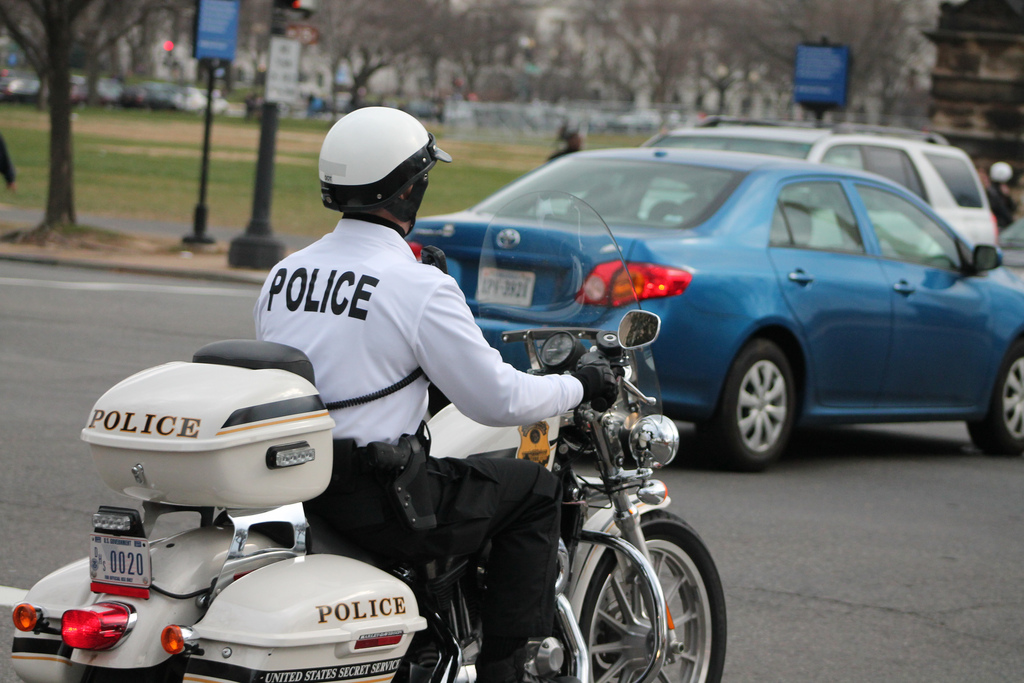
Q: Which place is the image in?
A: It is at the road.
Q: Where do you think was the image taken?
A: It was taken at the road.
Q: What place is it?
A: It is a road.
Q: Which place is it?
A: It is a road.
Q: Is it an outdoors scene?
A: Yes, it is outdoors.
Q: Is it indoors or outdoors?
A: It is outdoors.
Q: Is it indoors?
A: No, it is outdoors.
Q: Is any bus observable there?
A: No, there are no buses.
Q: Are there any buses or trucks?
A: No, there are no buses or trucks.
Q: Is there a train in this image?
A: No, there are no trains.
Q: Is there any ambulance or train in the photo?
A: No, there are no trains or ambulances.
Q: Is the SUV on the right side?
A: Yes, the SUV is on the right of the image.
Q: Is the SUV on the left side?
A: No, the SUV is on the right of the image.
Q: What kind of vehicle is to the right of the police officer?
A: The vehicle is a SUV.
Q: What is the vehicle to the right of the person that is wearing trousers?
A: The vehicle is a SUV.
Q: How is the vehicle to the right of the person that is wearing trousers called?
A: The vehicle is a SUV.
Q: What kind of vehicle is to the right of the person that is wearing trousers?
A: The vehicle is a SUV.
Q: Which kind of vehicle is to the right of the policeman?
A: The vehicle is a SUV.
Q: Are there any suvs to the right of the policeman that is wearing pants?
A: Yes, there is a SUV to the right of the policeman.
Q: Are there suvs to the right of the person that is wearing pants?
A: Yes, there is a SUV to the right of the policeman.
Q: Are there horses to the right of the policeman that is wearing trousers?
A: No, there is a SUV to the right of the policeman.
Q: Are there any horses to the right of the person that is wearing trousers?
A: No, there is a SUV to the right of the policeman.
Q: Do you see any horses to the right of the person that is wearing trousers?
A: No, there is a SUV to the right of the policeman.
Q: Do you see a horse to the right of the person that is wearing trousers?
A: No, there is a SUV to the right of the policeman.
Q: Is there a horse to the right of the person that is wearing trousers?
A: No, there is a SUV to the right of the policeman.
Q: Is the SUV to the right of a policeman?
A: Yes, the SUV is to the right of a policeman.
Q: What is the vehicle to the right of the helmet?
A: The vehicle is a SUV.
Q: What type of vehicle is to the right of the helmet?
A: The vehicle is a SUV.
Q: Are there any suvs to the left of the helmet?
A: No, the SUV is to the right of the helmet.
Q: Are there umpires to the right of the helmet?
A: No, there is a SUV to the right of the helmet.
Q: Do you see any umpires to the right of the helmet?
A: No, there is a SUV to the right of the helmet.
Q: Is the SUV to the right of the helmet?
A: Yes, the SUV is to the right of the helmet.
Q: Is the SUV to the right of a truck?
A: No, the SUV is to the right of the helmet.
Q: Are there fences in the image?
A: No, there are no fences.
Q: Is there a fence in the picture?
A: No, there are no fences.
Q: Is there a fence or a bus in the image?
A: No, there are no fences or buses.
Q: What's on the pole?
A: The sign is on the pole.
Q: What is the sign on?
A: The sign is on the pole.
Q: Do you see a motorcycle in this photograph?
A: Yes, there is a motorcycle.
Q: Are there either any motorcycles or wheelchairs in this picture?
A: Yes, there is a motorcycle.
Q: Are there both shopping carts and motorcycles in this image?
A: No, there is a motorcycle but no shopping carts.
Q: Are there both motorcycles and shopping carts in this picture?
A: No, there is a motorcycle but no shopping carts.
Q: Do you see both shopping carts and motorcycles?
A: No, there is a motorcycle but no shopping carts.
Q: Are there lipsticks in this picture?
A: No, there are no lipsticks.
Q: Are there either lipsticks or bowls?
A: No, there are no lipsticks or bowls.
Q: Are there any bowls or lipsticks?
A: No, there are no lipsticks or bowls.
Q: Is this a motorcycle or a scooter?
A: This is a motorcycle.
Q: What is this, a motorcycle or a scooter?
A: This is a motorcycle.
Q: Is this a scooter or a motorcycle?
A: This is a motorcycle.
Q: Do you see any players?
A: No, there are no players.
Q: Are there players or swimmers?
A: No, there are no players or swimmers.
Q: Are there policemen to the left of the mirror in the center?
A: Yes, there is a policeman to the left of the mirror.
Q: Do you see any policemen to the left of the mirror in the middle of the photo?
A: Yes, there is a policeman to the left of the mirror.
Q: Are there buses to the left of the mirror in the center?
A: No, there is a policeman to the left of the mirror.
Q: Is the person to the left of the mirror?
A: Yes, the policeman is to the left of the mirror.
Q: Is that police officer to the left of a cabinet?
A: No, the police officer is to the left of the mirror.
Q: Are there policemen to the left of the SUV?
A: Yes, there is a policeman to the left of the SUV.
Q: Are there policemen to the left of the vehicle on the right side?
A: Yes, there is a policeman to the left of the SUV.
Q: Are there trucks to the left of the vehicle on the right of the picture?
A: No, there is a policeman to the left of the SUV.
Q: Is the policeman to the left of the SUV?
A: Yes, the policeman is to the left of the SUV.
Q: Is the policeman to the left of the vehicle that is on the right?
A: Yes, the policeman is to the left of the SUV.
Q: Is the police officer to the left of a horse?
A: No, the police officer is to the left of the SUV.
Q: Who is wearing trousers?
A: The policeman is wearing trousers.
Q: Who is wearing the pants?
A: The policeman is wearing trousers.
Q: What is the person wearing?
A: The policeman is wearing pants.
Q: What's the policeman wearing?
A: The policeman is wearing pants.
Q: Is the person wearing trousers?
A: Yes, the policeman is wearing trousers.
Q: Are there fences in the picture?
A: No, there are no fences.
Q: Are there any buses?
A: No, there are no buses.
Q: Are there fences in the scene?
A: No, there are no fences.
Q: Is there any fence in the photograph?
A: No, there are no fences.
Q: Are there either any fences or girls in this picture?
A: No, there are no fences or girls.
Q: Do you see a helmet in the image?
A: Yes, there is a helmet.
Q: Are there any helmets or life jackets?
A: Yes, there is a helmet.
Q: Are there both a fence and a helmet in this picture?
A: No, there is a helmet but no fences.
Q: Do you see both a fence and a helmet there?
A: No, there is a helmet but no fences.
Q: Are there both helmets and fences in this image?
A: No, there is a helmet but no fences.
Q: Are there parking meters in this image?
A: No, there are no parking meters.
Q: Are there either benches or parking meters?
A: No, there are no parking meters or benches.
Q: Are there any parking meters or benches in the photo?
A: No, there are no parking meters or benches.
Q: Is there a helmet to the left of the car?
A: Yes, there is a helmet to the left of the car.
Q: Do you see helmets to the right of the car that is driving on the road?
A: No, the helmet is to the left of the car.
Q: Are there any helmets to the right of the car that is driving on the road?
A: No, the helmet is to the left of the car.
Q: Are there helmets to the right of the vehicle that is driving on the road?
A: No, the helmet is to the left of the car.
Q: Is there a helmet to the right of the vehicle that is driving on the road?
A: No, the helmet is to the left of the car.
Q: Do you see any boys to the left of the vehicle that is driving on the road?
A: No, there is a helmet to the left of the car.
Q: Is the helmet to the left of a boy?
A: No, the helmet is to the left of the car.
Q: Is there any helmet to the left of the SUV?
A: Yes, there is a helmet to the left of the SUV.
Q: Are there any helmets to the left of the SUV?
A: Yes, there is a helmet to the left of the SUV.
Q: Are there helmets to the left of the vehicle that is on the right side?
A: Yes, there is a helmet to the left of the SUV.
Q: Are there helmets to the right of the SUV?
A: No, the helmet is to the left of the SUV.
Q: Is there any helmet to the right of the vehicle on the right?
A: No, the helmet is to the left of the SUV.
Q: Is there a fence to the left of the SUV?
A: No, there is a helmet to the left of the SUV.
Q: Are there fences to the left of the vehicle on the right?
A: No, there is a helmet to the left of the SUV.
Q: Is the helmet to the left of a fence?
A: No, the helmet is to the left of a SUV.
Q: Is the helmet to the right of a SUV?
A: No, the helmet is to the left of a SUV.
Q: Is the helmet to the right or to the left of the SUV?
A: The helmet is to the left of the SUV.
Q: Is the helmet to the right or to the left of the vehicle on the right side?
A: The helmet is to the left of the SUV.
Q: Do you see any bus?
A: No, there are no buses.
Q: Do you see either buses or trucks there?
A: No, there are no buses or trucks.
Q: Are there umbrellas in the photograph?
A: No, there are no umbrellas.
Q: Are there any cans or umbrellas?
A: No, there are no umbrellas or cans.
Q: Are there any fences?
A: No, there are no fences.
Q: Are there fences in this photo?
A: No, there are no fences.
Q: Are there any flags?
A: No, there are no flags.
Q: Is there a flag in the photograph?
A: No, there are no flags.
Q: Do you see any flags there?
A: No, there are no flags.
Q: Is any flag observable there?
A: No, there are no flags.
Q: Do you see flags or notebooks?
A: No, there are no flags or notebooks.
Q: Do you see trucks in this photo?
A: No, there are no trucks.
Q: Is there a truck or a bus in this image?
A: No, there are no trucks or buses.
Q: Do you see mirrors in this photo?
A: Yes, there is a mirror.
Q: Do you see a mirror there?
A: Yes, there is a mirror.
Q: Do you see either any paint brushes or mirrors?
A: Yes, there is a mirror.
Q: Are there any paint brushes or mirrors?
A: Yes, there is a mirror.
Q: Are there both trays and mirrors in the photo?
A: No, there is a mirror but no trays.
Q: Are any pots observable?
A: No, there are no pots.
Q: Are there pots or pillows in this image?
A: No, there are no pots or pillows.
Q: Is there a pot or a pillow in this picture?
A: No, there are no pots or pillows.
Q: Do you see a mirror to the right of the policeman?
A: Yes, there is a mirror to the right of the policeman.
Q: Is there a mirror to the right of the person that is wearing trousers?
A: Yes, there is a mirror to the right of the policeman.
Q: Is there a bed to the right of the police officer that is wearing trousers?
A: No, there is a mirror to the right of the police officer.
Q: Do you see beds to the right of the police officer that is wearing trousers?
A: No, there is a mirror to the right of the police officer.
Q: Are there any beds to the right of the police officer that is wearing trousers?
A: No, there is a mirror to the right of the police officer.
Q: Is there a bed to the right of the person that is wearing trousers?
A: No, there is a mirror to the right of the police officer.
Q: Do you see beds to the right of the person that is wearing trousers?
A: No, there is a mirror to the right of the police officer.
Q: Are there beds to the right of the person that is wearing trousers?
A: No, there is a mirror to the right of the police officer.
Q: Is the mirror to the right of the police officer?
A: Yes, the mirror is to the right of the police officer.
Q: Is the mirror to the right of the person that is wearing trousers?
A: Yes, the mirror is to the right of the police officer.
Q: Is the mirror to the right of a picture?
A: No, the mirror is to the right of the police officer.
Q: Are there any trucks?
A: No, there are no trucks.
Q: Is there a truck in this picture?
A: No, there are no trucks.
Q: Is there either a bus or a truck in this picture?
A: No, there are no trucks or buses.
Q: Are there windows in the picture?
A: Yes, there is a window.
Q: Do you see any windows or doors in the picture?
A: Yes, there is a window.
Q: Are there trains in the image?
A: No, there are no trains.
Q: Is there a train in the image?
A: No, there are no trains.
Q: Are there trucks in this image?
A: No, there are no trucks.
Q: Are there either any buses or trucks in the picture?
A: No, there are no trucks or buses.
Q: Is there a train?
A: No, there are no trains.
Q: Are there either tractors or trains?
A: No, there are no trains or tractors.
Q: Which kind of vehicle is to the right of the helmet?
A: The vehicle is a car.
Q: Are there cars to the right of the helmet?
A: Yes, there is a car to the right of the helmet.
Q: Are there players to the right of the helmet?
A: No, there is a car to the right of the helmet.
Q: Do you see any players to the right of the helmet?
A: No, there is a car to the right of the helmet.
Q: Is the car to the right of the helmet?
A: Yes, the car is to the right of the helmet.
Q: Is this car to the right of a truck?
A: No, the car is to the right of the helmet.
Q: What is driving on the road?
A: The car is driving on the road.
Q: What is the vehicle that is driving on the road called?
A: The vehicle is a car.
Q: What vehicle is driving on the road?
A: The vehicle is a car.